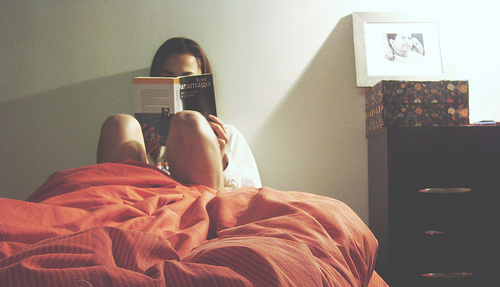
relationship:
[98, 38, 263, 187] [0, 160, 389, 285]
woman sitting on bed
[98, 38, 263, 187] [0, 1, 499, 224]
woman leaning against wall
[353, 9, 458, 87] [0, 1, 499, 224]
picture leaning against wall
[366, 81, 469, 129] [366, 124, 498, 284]
box on top of dresser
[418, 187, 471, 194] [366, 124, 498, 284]
handle on dresser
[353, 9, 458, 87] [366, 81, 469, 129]
picture on box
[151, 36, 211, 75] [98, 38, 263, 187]
hair of woman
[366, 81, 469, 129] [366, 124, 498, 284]
box on dresser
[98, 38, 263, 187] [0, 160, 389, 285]
woman in bed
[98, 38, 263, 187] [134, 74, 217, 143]
woman reading a book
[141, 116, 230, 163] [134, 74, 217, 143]
hands on book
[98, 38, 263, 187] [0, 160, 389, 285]
woman sitting in bed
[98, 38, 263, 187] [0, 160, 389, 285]
woman reading in bed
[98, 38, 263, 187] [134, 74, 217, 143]
woman relaxing with a book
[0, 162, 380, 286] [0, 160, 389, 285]
comforter on bed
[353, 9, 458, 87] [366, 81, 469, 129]
picture sitting on box